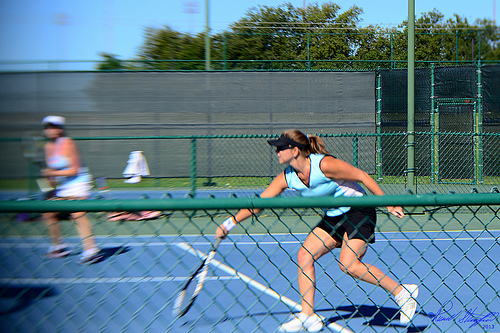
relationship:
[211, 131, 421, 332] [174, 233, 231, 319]
woman swinging racket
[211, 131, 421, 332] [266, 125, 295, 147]
woman wearing visor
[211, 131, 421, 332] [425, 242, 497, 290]
woman on court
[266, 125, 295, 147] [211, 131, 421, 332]
visor on woman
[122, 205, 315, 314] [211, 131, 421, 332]
fence near woman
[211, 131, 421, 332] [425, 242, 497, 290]
woman using court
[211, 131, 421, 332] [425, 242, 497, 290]
woman playing court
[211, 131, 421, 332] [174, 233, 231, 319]
woman holding racket